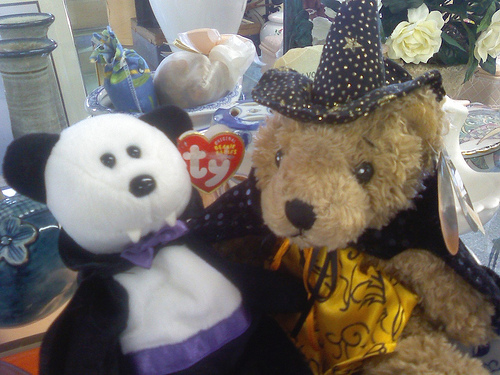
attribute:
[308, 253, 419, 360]
cloth — tied, small, blue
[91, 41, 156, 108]
bag — blue, tied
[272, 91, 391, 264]
bear — tan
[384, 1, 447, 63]
rose — small, light yellow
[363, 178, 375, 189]
ground — stuffed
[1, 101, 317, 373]
stuff toy — black, white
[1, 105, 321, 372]
stuffed bear — black, white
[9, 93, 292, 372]
bear — stuffed, black, white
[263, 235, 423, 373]
material — yellow, black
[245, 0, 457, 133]
hat — gold, blue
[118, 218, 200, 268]
tie — bow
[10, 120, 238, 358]
stuffed bear — black, white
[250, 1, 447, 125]
hat — dark, blue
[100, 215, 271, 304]
purple tie — small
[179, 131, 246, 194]
heart — red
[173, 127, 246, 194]
tag — red, white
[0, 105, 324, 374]
bear — black, white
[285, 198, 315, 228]
nose — black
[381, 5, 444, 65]
flower — white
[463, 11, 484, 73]
flower — white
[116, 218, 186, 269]
tie — purple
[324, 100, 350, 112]
star — yellow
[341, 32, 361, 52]
star — yellow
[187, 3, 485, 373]
bear — brown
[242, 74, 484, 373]
stuffed bear — brown